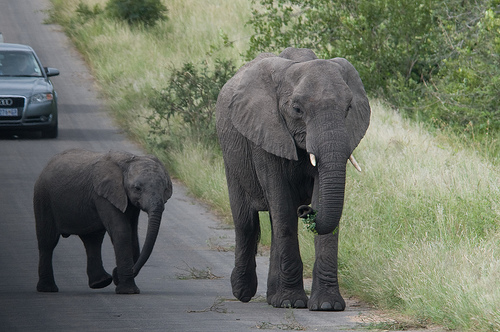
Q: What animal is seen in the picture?
A: Elephant.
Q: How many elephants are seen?
A: 2.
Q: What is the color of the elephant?
A: Grey.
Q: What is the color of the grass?
A: Green.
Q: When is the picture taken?
A: Daytime.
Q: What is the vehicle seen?
A: Car.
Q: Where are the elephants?
A: In the road.